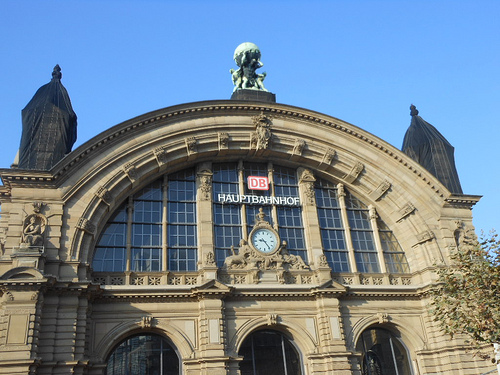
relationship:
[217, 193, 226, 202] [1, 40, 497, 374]
h on building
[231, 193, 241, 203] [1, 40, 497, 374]
u on building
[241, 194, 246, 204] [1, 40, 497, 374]
p on building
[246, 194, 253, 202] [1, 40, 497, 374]
t on building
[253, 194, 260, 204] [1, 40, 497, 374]
b on building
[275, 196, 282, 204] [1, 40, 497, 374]
n on building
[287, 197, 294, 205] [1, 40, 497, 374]
o on building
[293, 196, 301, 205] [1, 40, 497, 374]
f on building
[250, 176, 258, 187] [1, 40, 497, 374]
d on building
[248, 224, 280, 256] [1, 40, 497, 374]
clock on front of building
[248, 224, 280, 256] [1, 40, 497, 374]
clock on building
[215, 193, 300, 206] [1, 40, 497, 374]
name on building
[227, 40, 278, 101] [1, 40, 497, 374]
statue on top of building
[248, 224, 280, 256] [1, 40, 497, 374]
clock in middle of building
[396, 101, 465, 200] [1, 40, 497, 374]
tower on building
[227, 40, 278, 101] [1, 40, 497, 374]
statue on building